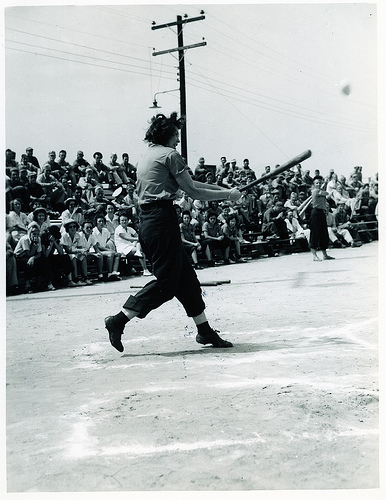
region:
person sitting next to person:
[60, 218, 94, 286]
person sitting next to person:
[77, 221, 105, 283]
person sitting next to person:
[92, 216, 120, 278]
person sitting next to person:
[113, 212, 152, 276]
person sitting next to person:
[103, 202, 122, 242]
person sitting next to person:
[202, 210, 235, 267]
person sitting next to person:
[179, 208, 219, 269]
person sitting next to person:
[220, 214, 248, 264]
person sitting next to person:
[263, 202, 288, 239]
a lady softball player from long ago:
[101, 108, 315, 360]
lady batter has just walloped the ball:
[132, 79, 359, 214]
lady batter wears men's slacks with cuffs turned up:
[114, 196, 213, 323]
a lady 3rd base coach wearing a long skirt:
[303, 170, 341, 265]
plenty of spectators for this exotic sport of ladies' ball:
[6, 140, 378, 301]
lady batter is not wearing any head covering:
[139, 108, 186, 151]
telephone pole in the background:
[140, 5, 211, 167]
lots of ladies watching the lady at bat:
[59, 211, 151, 277]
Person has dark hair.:
[155, 123, 183, 147]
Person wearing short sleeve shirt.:
[132, 159, 189, 187]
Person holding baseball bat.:
[216, 173, 276, 206]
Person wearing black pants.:
[146, 222, 170, 261]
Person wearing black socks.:
[111, 310, 134, 336]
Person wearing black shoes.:
[100, 322, 133, 365]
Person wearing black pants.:
[307, 214, 334, 242]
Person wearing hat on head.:
[63, 218, 78, 225]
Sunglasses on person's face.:
[81, 223, 92, 229]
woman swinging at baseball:
[102, 92, 319, 346]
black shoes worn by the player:
[98, 314, 231, 355]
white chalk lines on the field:
[62, 326, 384, 459]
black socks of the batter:
[116, 309, 212, 332]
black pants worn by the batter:
[123, 203, 206, 314]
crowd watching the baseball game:
[9, 143, 374, 301]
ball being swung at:
[341, 75, 352, 96]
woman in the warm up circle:
[296, 178, 335, 261]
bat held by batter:
[230, 151, 312, 191]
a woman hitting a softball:
[85, 71, 359, 361]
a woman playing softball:
[97, 100, 315, 368]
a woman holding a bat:
[103, 103, 321, 358]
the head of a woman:
[140, 107, 189, 155]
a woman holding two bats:
[299, 168, 344, 265]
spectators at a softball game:
[9, 145, 363, 260]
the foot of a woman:
[186, 321, 240, 355]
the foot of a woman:
[99, 312, 132, 356]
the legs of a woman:
[80, 233, 243, 373]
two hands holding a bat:
[223, 178, 246, 210]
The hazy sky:
[7, 10, 379, 187]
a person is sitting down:
[13, 223, 48, 291]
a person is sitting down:
[41, 225, 71, 282]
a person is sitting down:
[59, 213, 90, 279]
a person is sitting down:
[76, 217, 102, 279]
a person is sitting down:
[92, 216, 123, 280]